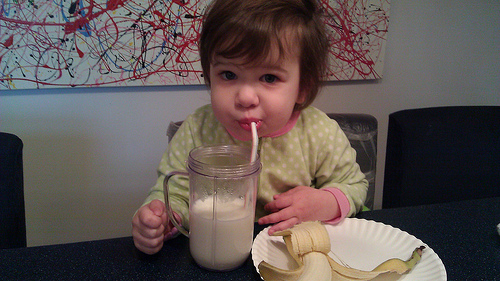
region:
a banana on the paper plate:
[288, 227, 332, 278]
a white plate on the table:
[348, 226, 387, 263]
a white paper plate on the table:
[353, 224, 387, 251]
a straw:
[245, 125, 262, 156]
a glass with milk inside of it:
[193, 155, 250, 252]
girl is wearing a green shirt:
[186, 115, 207, 140]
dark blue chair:
[390, 112, 463, 172]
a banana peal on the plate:
[377, 254, 414, 276]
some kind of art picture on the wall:
[53, 22, 100, 83]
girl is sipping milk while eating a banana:
[176, 17, 341, 267]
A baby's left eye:
[257, 69, 285, 88]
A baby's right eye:
[213, 68, 240, 83]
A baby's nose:
[232, 84, 262, 112]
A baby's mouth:
[232, 112, 262, 132]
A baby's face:
[213, 28, 288, 136]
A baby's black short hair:
[199, 0, 325, 115]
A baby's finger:
[262, 198, 290, 208]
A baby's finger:
[257, 207, 292, 224]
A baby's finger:
[266, 219, 296, 234]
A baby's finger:
[147, 196, 163, 217]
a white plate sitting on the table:
[253, 219, 449, 279]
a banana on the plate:
[272, 223, 428, 279]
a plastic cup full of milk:
[163, 147, 256, 269]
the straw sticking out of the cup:
[247, 119, 259, 160]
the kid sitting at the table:
[134, 1, 364, 243]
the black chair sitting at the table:
[383, 107, 490, 202]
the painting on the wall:
[3, 1, 395, 88]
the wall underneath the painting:
[17, 98, 153, 230]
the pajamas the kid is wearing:
[163, 100, 366, 230]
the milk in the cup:
[186, 198, 253, 264]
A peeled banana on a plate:
[256, 230, 458, 279]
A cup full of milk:
[159, 127, 267, 279]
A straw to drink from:
[239, 117, 271, 194]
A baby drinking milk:
[124, 0, 359, 263]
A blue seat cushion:
[383, 69, 498, 221]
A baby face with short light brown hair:
[179, 2, 341, 157]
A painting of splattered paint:
[2, 0, 400, 105]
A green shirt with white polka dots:
[117, 103, 382, 220]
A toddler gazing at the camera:
[126, 2, 357, 264]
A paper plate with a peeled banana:
[252, 207, 462, 277]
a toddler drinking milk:
[136, 0, 370, 248]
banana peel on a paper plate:
[252, 217, 448, 279]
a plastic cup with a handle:
[163, 121, 260, 268]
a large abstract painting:
[0, 0, 382, 79]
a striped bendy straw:
[247, 120, 260, 213]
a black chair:
[383, 104, 499, 220]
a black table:
[6, 196, 498, 278]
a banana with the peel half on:
[257, 220, 423, 279]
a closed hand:
[131, 200, 171, 254]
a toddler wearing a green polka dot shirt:
[131, 0, 368, 226]